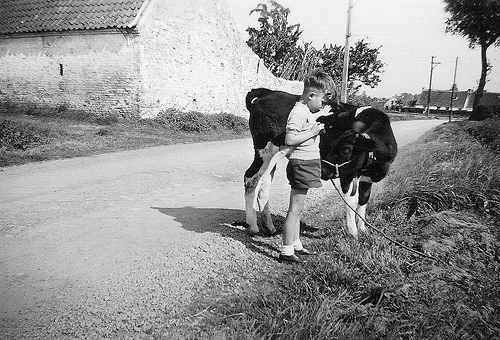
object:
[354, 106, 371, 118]
patch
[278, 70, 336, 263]
boy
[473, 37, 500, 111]
branch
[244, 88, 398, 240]
calf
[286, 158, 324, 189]
shorts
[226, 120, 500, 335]
grass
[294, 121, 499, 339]
vegetation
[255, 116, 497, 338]
grassy vegetation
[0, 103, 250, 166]
grassy vegetation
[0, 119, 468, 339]
road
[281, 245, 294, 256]
sock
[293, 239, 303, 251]
sock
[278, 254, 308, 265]
shoe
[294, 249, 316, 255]
shoe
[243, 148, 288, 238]
legs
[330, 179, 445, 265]
rope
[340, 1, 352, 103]
pole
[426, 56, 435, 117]
pole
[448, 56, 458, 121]
pole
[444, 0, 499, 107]
tree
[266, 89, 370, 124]
back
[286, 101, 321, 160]
shirt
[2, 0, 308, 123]
house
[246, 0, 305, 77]
tree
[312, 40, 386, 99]
tree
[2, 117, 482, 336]
ground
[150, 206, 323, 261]
shadow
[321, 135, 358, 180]
face